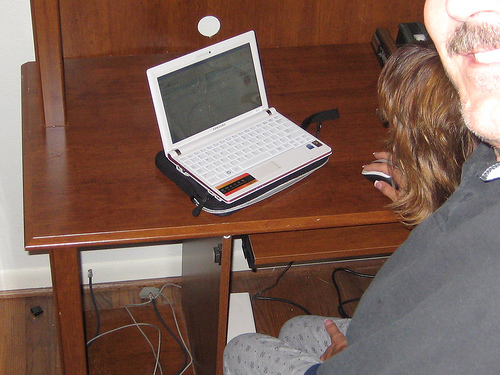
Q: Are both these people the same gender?
A: No, they are both male and female.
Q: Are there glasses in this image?
A: No, there are no glasses.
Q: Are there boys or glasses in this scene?
A: No, there are no glasses or boys.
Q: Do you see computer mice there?
A: Yes, there is a computer mouse.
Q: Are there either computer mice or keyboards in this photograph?
A: Yes, there is a computer mouse.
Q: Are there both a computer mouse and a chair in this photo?
A: No, there is a computer mouse but no chairs.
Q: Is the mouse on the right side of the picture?
A: Yes, the mouse is on the right of the image.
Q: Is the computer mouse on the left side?
A: No, the computer mouse is on the right of the image.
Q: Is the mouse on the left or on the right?
A: The mouse is on the right of the image.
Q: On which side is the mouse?
A: The mouse is on the right of the image.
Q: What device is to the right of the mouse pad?
A: The device is a computer mouse.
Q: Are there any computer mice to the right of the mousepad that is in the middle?
A: Yes, there is a computer mouse to the right of the mouse pad.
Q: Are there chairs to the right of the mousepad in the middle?
A: No, there is a computer mouse to the right of the mouse pad.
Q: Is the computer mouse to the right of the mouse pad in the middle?
A: Yes, the computer mouse is to the right of the mousepad.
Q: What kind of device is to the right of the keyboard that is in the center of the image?
A: The device is a computer mouse.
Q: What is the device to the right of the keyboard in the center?
A: The device is a computer mouse.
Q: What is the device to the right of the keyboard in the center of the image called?
A: The device is a computer mouse.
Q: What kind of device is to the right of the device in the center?
A: The device is a computer mouse.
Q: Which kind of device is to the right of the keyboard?
A: The device is a computer mouse.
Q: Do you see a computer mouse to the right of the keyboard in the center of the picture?
A: Yes, there is a computer mouse to the right of the keyboard.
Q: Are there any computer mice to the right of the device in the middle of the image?
A: Yes, there is a computer mouse to the right of the keyboard.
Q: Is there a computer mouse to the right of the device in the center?
A: Yes, there is a computer mouse to the right of the keyboard.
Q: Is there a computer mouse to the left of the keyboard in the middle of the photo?
A: No, the computer mouse is to the right of the keyboard.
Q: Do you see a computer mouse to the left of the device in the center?
A: No, the computer mouse is to the right of the keyboard.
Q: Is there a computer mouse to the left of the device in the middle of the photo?
A: No, the computer mouse is to the right of the keyboard.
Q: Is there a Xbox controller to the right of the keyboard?
A: No, there is a computer mouse to the right of the keyboard.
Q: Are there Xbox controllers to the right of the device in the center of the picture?
A: No, there is a computer mouse to the right of the keyboard.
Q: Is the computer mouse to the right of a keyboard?
A: Yes, the computer mouse is to the right of a keyboard.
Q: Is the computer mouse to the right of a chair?
A: No, the computer mouse is to the right of a keyboard.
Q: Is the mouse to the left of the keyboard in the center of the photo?
A: No, the mouse is to the right of the keyboard.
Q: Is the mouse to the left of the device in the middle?
A: No, the mouse is to the right of the keyboard.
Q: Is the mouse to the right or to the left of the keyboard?
A: The mouse is to the right of the keyboard.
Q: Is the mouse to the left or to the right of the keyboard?
A: The mouse is to the right of the keyboard.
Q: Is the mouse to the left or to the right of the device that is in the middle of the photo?
A: The mouse is to the right of the keyboard.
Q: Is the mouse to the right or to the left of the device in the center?
A: The mouse is to the right of the keyboard.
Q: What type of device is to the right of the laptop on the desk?
A: The device is a computer mouse.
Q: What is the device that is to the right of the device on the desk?
A: The device is a computer mouse.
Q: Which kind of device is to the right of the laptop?
A: The device is a computer mouse.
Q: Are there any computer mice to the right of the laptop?
A: Yes, there is a computer mouse to the right of the laptop.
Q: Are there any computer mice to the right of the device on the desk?
A: Yes, there is a computer mouse to the right of the laptop.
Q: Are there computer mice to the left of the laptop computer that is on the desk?
A: No, the computer mouse is to the right of the laptop.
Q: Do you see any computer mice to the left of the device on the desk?
A: No, the computer mouse is to the right of the laptop.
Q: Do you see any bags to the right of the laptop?
A: No, there is a computer mouse to the right of the laptop.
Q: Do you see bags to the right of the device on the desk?
A: No, there is a computer mouse to the right of the laptop.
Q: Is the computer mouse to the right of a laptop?
A: Yes, the computer mouse is to the right of a laptop.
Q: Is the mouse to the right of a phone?
A: No, the mouse is to the right of a laptop.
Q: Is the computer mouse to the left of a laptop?
A: No, the computer mouse is to the right of a laptop.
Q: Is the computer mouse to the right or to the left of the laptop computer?
A: The computer mouse is to the right of the laptop computer.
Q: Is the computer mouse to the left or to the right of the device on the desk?
A: The computer mouse is to the right of the laptop computer.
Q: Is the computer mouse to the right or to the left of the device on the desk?
A: The computer mouse is to the right of the laptop computer.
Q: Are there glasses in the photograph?
A: No, there are no glasses.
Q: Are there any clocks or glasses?
A: No, there are no glasses or clocks.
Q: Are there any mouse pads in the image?
A: Yes, there is a mouse pad.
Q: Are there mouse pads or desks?
A: Yes, there is a mouse pad.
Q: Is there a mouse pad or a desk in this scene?
A: Yes, there is a mouse pad.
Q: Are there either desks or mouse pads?
A: Yes, there is a mouse pad.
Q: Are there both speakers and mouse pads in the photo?
A: No, there is a mouse pad but no speakers.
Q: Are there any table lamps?
A: No, there are no table lamps.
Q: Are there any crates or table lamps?
A: No, there are no table lamps or crates.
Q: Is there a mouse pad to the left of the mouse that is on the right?
A: Yes, there is a mouse pad to the left of the mouse.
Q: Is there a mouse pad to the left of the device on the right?
A: Yes, there is a mouse pad to the left of the mouse.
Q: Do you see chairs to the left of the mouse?
A: No, there is a mouse pad to the left of the mouse.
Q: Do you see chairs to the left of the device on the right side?
A: No, there is a mouse pad to the left of the mouse.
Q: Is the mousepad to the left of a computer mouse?
A: Yes, the mousepad is to the left of a computer mouse.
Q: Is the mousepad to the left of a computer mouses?
A: No, the mousepad is to the left of a computer mouse.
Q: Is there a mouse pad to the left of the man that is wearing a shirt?
A: Yes, there is a mouse pad to the left of the man.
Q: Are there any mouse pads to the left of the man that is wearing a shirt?
A: Yes, there is a mouse pad to the left of the man.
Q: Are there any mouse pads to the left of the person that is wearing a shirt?
A: Yes, there is a mouse pad to the left of the man.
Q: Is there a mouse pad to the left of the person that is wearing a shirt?
A: Yes, there is a mouse pad to the left of the man.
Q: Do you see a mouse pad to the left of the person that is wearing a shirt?
A: Yes, there is a mouse pad to the left of the man.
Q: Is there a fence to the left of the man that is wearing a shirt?
A: No, there is a mouse pad to the left of the man.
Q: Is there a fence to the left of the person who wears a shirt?
A: No, there is a mouse pad to the left of the man.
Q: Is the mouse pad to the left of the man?
A: Yes, the mouse pad is to the left of the man.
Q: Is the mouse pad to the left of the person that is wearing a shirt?
A: Yes, the mouse pad is to the left of the man.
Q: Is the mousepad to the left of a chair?
A: No, the mousepad is to the left of the man.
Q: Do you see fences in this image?
A: No, there are no fences.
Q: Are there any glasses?
A: No, there are no glasses.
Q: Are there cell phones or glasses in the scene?
A: No, there are no glasses or cell phones.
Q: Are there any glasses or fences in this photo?
A: No, there are no glasses or fences.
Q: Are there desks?
A: Yes, there is a desk.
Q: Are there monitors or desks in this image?
A: Yes, there is a desk.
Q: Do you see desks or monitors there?
A: Yes, there is a desk.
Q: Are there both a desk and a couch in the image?
A: No, there is a desk but no couches.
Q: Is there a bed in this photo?
A: No, there are no beds.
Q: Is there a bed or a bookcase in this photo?
A: No, there are no beds or bookcases.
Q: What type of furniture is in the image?
A: The furniture is a desk.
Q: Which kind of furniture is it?
A: The piece of furniture is a desk.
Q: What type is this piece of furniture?
A: This is a desk.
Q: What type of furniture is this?
A: This is a desk.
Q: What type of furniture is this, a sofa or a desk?
A: This is a desk.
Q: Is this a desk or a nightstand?
A: This is a desk.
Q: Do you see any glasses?
A: No, there are no glasses.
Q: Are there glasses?
A: No, there are no glasses.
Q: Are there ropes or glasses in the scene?
A: No, there are no glasses or ropes.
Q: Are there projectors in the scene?
A: No, there are no projectors.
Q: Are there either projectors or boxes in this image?
A: No, there are no projectors or boxes.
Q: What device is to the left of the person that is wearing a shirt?
A: The device is a screen.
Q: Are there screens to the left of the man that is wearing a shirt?
A: Yes, there is a screen to the left of the man.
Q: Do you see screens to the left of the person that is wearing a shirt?
A: Yes, there is a screen to the left of the man.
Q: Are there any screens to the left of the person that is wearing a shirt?
A: Yes, there is a screen to the left of the man.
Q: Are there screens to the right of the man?
A: No, the screen is to the left of the man.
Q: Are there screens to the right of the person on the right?
A: No, the screen is to the left of the man.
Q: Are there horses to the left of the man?
A: No, there is a screen to the left of the man.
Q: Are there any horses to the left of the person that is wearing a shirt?
A: No, there is a screen to the left of the man.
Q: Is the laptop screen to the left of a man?
A: Yes, the screen is to the left of a man.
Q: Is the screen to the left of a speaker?
A: No, the screen is to the left of a man.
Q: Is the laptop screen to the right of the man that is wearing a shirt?
A: No, the screen is to the left of the man.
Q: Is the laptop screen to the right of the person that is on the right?
A: No, the screen is to the left of the man.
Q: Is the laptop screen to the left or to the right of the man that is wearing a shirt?
A: The screen is to the left of the man.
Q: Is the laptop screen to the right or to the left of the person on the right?
A: The screen is to the left of the man.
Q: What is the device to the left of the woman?
A: The device is a screen.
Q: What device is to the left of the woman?
A: The device is a screen.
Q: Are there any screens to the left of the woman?
A: Yes, there is a screen to the left of the woman.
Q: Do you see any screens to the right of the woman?
A: No, the screen is to the left of the woman.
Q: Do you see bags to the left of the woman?
A: No, there is a screen to the left of the woman.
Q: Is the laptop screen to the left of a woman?
A: Yes, the screen is to the left of a woman.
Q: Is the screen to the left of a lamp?
A: No, the screen is to the left of a woman.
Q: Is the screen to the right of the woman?
A: No, the screen is to the left of the woman.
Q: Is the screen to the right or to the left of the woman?
A: The screen is to the left of the woman.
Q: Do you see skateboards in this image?
A: No, there are no skateboards.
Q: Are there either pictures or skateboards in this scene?
A: No, there are no skateboards or pictures.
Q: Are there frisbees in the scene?
A: No, there are no frisbees.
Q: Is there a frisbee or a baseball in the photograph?
A: No, there are no frisbees or baseballs.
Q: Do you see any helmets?
A: No, there are no helmets.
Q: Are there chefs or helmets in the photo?
A: No, there are no helmets or chefs.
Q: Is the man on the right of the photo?
A: Yes, the man is on the right of the image.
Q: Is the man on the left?
A: No, the man is on the right of the image.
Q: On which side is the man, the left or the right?
A: The man is on the right of the image.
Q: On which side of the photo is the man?
A: The man is on the right of the image.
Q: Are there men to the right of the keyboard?
A: Yes, there is a man to the right of the keyboard.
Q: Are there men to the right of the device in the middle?
A: Yes, there is a man to the right of the keyboard.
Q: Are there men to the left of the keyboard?
A: No, the man is to the right of the keyboard.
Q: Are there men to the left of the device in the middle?
A: No, the man is to the right of the keyboard.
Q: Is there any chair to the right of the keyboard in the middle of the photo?
A: No, there is a man to the right of the keyboard.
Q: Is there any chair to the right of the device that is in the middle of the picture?
A: No, there is a man to the right of the keyboard.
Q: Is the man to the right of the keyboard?
A: Yes, the man is to the right of the keyboard.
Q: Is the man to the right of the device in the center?
A: Yes, the man is to the right of the keyboard.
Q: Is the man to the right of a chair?
A: No, the man is to the right of the keyboard.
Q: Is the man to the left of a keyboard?
A: No, the man is to the right of a keyboard.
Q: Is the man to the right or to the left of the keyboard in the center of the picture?
A: The man is to the right of the keyboard.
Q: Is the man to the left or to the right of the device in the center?
A: The man is to the right of the keyboard.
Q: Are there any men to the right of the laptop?
A: Yes, there is a man to the right of the laptop.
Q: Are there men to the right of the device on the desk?
A: Yes, there is a man to the right of the laptop.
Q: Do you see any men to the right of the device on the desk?
A: Yes, there is a man to the right of the laptop.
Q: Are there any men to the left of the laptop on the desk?
A: No, the man is to the right of the laptop.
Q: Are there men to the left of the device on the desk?
A: No, the man is to the right of the laptop.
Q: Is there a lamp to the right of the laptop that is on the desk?
A: No, there is a man to the right of the laptop.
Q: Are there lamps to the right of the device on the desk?
A: No, there is a man to the right of the laptop.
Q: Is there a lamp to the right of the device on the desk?
A: No, there is a man to the right of the laptop.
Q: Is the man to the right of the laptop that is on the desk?
A: Yes, the man is to the right of the laptop.